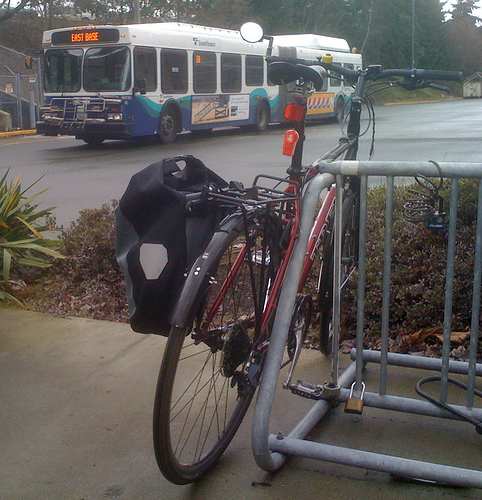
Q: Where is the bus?
A: On the road.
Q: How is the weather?
A: Rainy.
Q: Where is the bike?
A: Next to the bike rack.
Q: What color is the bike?
A: Red.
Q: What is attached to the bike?
A: A backpack.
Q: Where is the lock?
A: Near the bottom of the bike rack.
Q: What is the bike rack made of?
A: Steel.